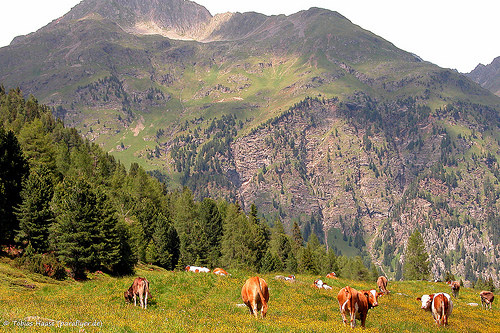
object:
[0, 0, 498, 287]
mountain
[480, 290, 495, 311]
cows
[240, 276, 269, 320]
cow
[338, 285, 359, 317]
back side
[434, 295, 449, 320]
back side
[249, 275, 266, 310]
back side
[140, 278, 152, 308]
back side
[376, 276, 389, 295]
cow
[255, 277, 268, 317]
tail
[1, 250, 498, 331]
grass field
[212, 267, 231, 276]
cow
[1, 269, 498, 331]
grass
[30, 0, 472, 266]
green grass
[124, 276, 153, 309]
cow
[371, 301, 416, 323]
flowers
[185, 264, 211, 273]
cow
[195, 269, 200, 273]
spots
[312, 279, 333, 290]
cow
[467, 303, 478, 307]
rock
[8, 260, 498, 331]
field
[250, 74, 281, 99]
grass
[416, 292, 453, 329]
brown cow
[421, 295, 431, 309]
white face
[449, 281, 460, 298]
cows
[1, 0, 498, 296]
mountain side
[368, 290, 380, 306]
face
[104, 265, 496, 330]
cows/field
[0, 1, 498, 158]
mountains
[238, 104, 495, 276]
cliff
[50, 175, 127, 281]
tree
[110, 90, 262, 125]
grass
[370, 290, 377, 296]
spot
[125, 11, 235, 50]
sunshine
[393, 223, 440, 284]
tree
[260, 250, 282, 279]
tree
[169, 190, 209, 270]
tree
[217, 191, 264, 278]
tree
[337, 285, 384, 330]
cow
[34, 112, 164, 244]
tree